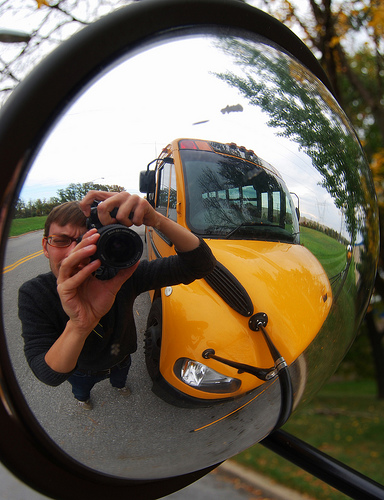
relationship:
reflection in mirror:
[2, 30, 378, 476] [0, 1, 382, 495]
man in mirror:
[19, 190, 217, 410] [0, 1, 382, 495]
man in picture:
[19, 190, 217, 410] [0, 0, 379, 499]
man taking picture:
[19, 190, 217, 410] [0, 0, 379, 499]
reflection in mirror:
[2, 92, 378, 476] [2, 92, 380, 498]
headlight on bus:
[171, 351, 238, 392] [119, 141, 337, 404]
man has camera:
[19, 190, 217, 410] [76, 198, 147, 280]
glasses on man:
[41, 233, 78, 253] [19, 190, 217, 410]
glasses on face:
[41, 233, 78, 253] [46, 222, 82, 277]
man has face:
[19, 190, 217, 410] [46, 222, 82, 277]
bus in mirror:
[138, 137, 333, 407] [0, 1, 382, 495]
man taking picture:
[19, 190, 217, 410] [133, 138, 336, 436]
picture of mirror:
[133, 138, 336, 436] [0, 1, 382, 495]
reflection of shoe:
[2, 30, 378, 476] [76, 393, 94, 414]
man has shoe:
[19, 190, 217, 410] [76, 393, 94, 414]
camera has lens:
[76, 198, 147, 280] [96, 231, 146, 266]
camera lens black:
[76, 205, 147, 273] [142, 263, 173, 277]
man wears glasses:
[19, 190, 217, 410] [39, 226, 78, 251]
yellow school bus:
[270, 278, 311, 319] [135, 125, 347, 407]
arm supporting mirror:
[108, 187, 226, 272] [11, 38, 370, 457]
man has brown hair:
[19, 190, 217, 410] [55, 209, 84, 223]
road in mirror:
[6, 243, 46, 276] [0, 1, 382, 495]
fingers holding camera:
[61, 235, 105, 288] [87, 194, 146, 276]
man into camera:
[19, 190, 217, 410] [76, 198, 147, 280]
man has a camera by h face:
[19, 190, 217, 410] [36, 219, 99, 272]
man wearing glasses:
[19, 190, 217, 410] [42, 233, 75, 250]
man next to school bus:
[19, 190, 217, 410] [138, 137, 333, 407]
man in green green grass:
[19, 190, 217, 410] [228, 323, 384, 500]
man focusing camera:
[19, 190, 217, 410] [83, 208, 153, 281]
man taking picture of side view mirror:
[19, 190, 217, 410] [0, 1, 382, 495]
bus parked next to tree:
[135, 125, 347, 407] [307, 0, 382, 365]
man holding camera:
[19, 190, 217, 410] [80, 208, 142, 276]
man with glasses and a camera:
[19, 190, 173, 402] [87, 194, 146, 276]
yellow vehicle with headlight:
[158, 235, 335, 396] [171, 353, 243, 395]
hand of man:
[50, 231, 104, 384] [25, 195, 179, 403]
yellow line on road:
[7, 247, 40, 272] [6, 233, 46, 275]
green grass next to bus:
[337, 393, 373, 420] [147, 126, 335, 412]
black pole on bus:
[289, 437, 367, 491] [135, 125, 347, 407]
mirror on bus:
[137, 166, 165, 199] [116, 128, 358, 409]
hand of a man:
[55, 225, 141, 328] [30, 191, 127, 299]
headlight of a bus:
[171, 353, 243, 395] [116, 128, 358, 409]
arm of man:
[30, 281, 107, 386] [32, 194, 146, 312]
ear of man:
[35, 229, 72, 277] [30, 196, 138, 312]